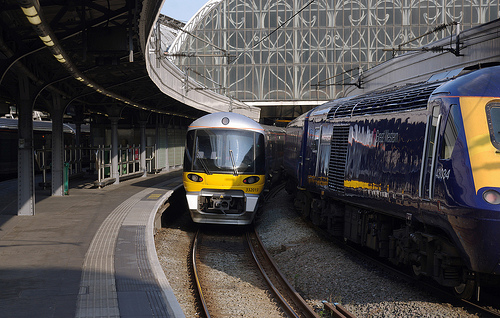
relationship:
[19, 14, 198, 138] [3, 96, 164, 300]
lights at station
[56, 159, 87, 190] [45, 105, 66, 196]
can by pole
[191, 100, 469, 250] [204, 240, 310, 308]
trains on railroad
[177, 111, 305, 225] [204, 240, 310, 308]
train on railroad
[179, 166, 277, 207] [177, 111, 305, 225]
headlights on train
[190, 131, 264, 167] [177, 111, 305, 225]
windshield on train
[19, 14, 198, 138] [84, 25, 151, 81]
lights on ceiling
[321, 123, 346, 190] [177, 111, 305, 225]
vents on train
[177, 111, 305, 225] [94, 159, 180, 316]
train at platform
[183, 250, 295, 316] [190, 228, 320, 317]
pantographs over railroad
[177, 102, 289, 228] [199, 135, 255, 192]
train has wipers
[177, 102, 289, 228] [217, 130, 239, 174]
train has wiper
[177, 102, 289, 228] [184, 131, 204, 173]
train has wiper